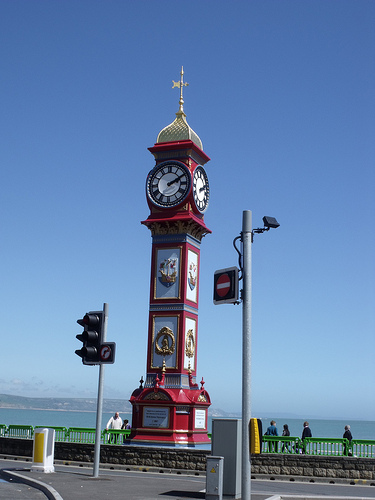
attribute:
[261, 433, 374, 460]
fence — green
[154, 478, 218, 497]
shadow — dark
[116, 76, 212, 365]
tower — white, red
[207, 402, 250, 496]
boxes — are gray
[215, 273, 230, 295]
circle — red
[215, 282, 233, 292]
line — white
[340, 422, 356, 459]
person — walking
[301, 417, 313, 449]
person — walking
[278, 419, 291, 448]
person — walking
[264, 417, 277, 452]
person — walking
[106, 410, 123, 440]
person — walking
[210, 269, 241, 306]
sign — red, white, black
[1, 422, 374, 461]
fence — green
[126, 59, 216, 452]
tower — is direction, red, white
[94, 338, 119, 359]
sign — street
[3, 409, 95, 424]
water — large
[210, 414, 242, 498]
electrical box — gray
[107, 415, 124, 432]
sweater — white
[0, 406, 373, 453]
water — large, body of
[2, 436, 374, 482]
wall — green, gray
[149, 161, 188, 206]
clock — black, white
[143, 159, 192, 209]
clock — white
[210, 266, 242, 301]
sign — red, white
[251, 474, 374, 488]
road curb — rounded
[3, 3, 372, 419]
sky — blue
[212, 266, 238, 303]
sign — street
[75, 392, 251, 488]
bridge — brick, gray, concrete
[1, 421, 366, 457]
railing — green, metal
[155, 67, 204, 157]
spire — gold